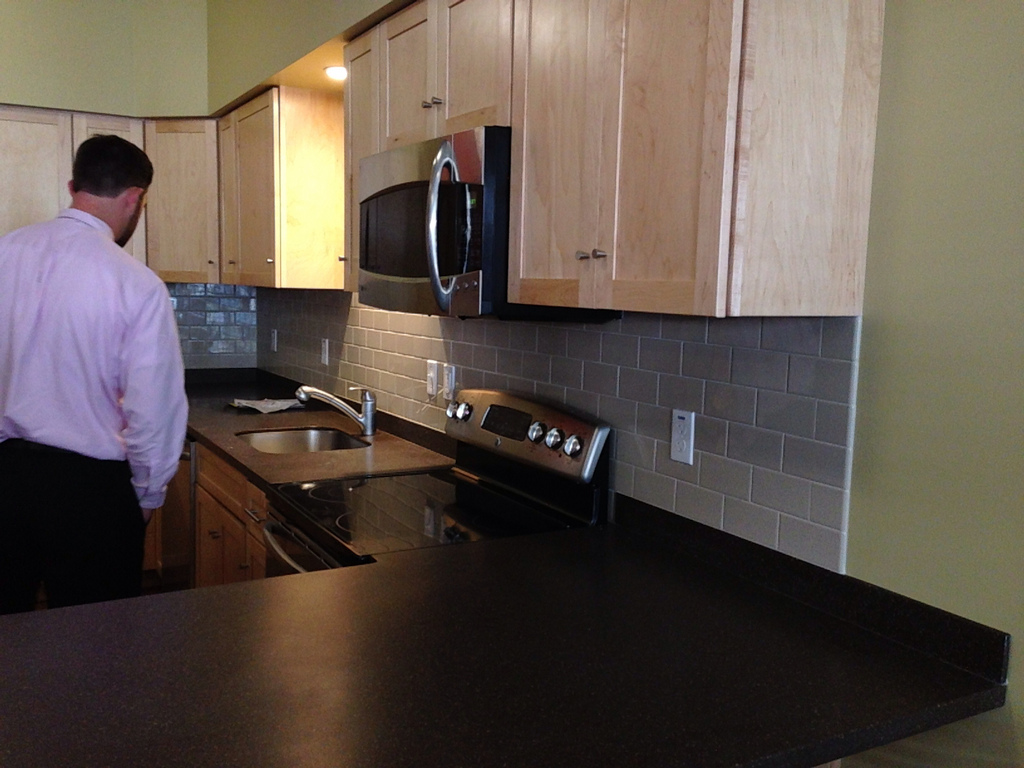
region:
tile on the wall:
[794, 537, 829, 563]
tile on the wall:
[807, 476, 849, 530]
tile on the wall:
[804, 452, 852, 482]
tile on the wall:
[810, 410, 839, 440]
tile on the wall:
[817, 363, 849, 390]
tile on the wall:
[817, 335, 852, 359]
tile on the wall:
[746, 509, 785, 533]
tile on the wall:
[535, 332, 565, 356]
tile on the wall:
[399, 339, 407, 372]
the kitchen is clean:
[2, 0, 1021, 766]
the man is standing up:
[1, 133, 191, 615]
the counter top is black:
[0, 366, 1010, 765]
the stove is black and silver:
[263, 388, 615, 581]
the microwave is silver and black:
[355, 123, 621, 329]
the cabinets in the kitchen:
[1, 0, 1022, 766]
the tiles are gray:
[156, 279, 859, 575]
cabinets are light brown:
[351, 26, 851, 344]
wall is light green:
[942, 146, 1018, 426]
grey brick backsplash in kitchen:
[716, 354, 862, 535]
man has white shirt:
[0, 211, 175, 427]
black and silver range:
[125, 395, 730, 582]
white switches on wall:
[412, 351, 537, 476]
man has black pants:
[0, 380, 99, 619]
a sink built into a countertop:
[194, 364, 520, 523]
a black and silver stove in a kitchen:
[219, 366, 671, 658]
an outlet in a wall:
[636, 332, 772, 549]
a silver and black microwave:
[330, 66, 713, 335]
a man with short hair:
[4, 88, 229, 516]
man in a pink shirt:
[1, 129, 183, 595]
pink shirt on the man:
[1, 206, 186, 507]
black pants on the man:
[0, 442, 150, 604]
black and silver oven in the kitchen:
[260, 382, 612, 583]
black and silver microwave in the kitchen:
[351, 133, 621, 329]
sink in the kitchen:
[231, 383, 384, 457]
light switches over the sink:
[418, 361, 461, 400]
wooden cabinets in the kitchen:
[4, 0, 886, 324]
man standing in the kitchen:
[0, 136, 185, 602]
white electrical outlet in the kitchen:
[665, 404, 698, 469]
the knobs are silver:
[435, 392, 591, 462]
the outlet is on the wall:
[653, 392, 743, 526]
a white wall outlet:
[665, 407, 705, 465]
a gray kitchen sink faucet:
[285, 373, 383, 444]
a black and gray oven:
[257, 380, 613, 580]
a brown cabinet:
[187, 486, 268, 591]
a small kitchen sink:
[231, 423, 353, 455]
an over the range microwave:
[345, 120, 522, 323]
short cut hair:
[68, 127, 161, 205]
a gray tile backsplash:
[242, 298, 854, 565]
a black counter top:
[2, 534, 1020, 766]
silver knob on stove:
[517, 416, 550, 449]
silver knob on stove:
[559, 433, 583, 468]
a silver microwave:
[348, 149, 481, 306]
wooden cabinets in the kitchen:
[148, 3, 876, 317]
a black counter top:
[34, 535, 1000, 748]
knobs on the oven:
[442, 395, 594, 473]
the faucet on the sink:
[297, 383, 383, 432]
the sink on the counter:
[245, 427, 375, 447]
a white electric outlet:
[672, 411, 696, 459]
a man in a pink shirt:
[2, 146, 189, 555]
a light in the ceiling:
[326, 62, 345, 85]